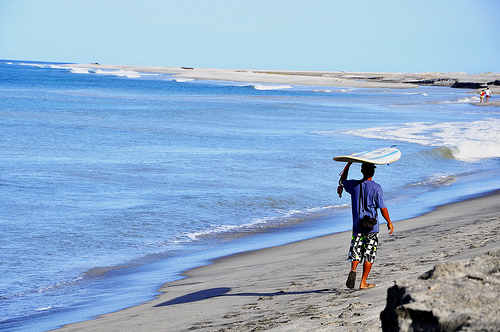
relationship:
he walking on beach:
[338, 159, 395, 290] [49, 190, 499, 330]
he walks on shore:
[338, 159, 395, 290] [0, 178, 499, 328]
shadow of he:
[151, 286, 342, 307] [338, 159, 395, 290]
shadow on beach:
[151, 286, 342, 307] [49, 190, 499, 330]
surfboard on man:
[330, 148, 401, 166] [331, 164, 391, 262]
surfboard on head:
[330, 148, 401, 166] [355, 158, 379, 181]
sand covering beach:
[113, 200, 498, 331] [92, 87, 495, 328]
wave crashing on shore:
[346, 103, 498, 170] [31, 191, 498, 322]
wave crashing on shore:
[4, 53, 448, 98] [31, 191, 498, 322]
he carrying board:
[338, 159, 395, 290] [331, 132, 413, 167]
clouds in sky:
[0, 0, 500, 73] [0, 0, 500, 74]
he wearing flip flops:
[338, 159, 395, 290] [342, 267, 379, 290]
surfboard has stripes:
[330, 148, 401, 166] [328, 131, 398, 190]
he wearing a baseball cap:
[338, 159, 392, 289] [358, 160, 376, 168]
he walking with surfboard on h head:
[338, 159, 395, 290] [357, 160, 377, 181]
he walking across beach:
[338, 159, 395, 290] [125, 184, 489, 330]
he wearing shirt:
[338, 159, 395, 290] [343, 177, 386, 232]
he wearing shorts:
[338, 159, 395, 290] [347, 232, 379, 262]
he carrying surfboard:
[338, 159, 395, 290] [338, 149, 403, 163]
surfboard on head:
[330, 144, 409, 166] [356, 161, 378, 178]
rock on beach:
[378, 247, 498, 329] [175, 183, 496, 327]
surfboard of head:
[330, 148, 401, 166] [361, 159, 375, 179]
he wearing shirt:
[338, 159, 395, 290] [338, 179, 406, 239]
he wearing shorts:
[338, 159, 395, 290] [347, 223, 377, 263]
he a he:
[338, 159, 395, 290] [338, 159, 395, 290]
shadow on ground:
[151, 278, 353, 308] [234, 266, 467, 331]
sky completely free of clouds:
[0, 0, 500, 74] [106, 54, 302, 180]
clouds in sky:
[0, 0, 500, 73] [370, 16, 427, 61]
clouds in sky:
[258, 27, 348, 66] [19, 8, 479, 76]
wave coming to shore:
[346, 115, 500, 162] [7, 193, 289, 290]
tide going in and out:
[1, 177, 329, 304] [106, 228, 296, 332]